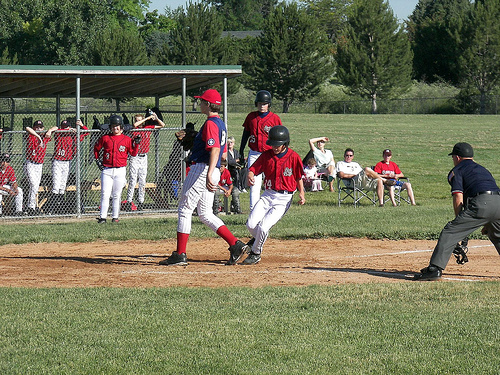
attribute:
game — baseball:
[2, 38, 472, 274]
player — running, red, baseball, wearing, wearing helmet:
[229, 82, 341, 280]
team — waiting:
[10, 105, 187, 248]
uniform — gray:
[439, 160, 494, 228]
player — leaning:
[126, 95, 179, 221]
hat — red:
[183, 83, 231, 118]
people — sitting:
[306, 121, 398, 193]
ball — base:
[232, 244, 372, 320]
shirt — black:
[452, 164, 496, 206]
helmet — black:
[274, 127, 292, 137]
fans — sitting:
[0, 183, 93, 253]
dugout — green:
[96, 57, 221, 117]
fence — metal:
[55, 134, 88, 187]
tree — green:
[274, 23, 376, 106]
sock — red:
[172, 219, 199, 261]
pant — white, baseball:
[159, 178, 197, 224]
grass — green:
[365, 131, 419, 158]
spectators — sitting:
[2, 73, 215, 204]